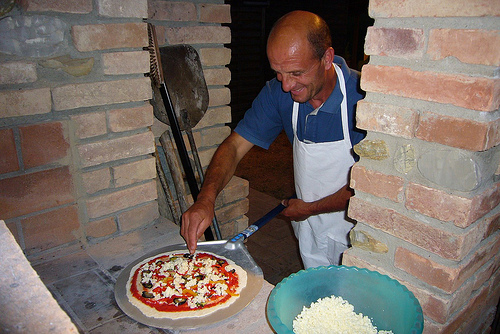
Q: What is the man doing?
A: Making pizza.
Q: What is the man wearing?
A: Apron.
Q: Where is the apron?
A: On the man.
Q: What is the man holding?
A: Handle.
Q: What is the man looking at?
A: Pizza.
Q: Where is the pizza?
A: In front of man.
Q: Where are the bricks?
A: Next to man.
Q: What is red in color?
A: Bricks.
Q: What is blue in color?
A: Shirt.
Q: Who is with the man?
A: No people.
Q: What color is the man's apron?
A: White.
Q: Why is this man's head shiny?
A: He's balding.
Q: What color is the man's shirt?
A: Blue.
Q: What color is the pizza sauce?
A: Red.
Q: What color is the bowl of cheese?
A: Blue.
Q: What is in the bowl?
A: Cheese.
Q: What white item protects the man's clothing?
A: An apron.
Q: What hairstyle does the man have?
A: Balding.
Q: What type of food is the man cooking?
A: Pizza.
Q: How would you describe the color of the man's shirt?
A: Blue.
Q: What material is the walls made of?
A: Brick and mortar.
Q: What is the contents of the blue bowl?
A: Cheese.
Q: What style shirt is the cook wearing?
A: Polo.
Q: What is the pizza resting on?
A: An oven paddle.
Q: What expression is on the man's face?
A: A smile.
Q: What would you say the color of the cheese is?
A: White.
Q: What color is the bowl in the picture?
A: Blue.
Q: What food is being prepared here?
A: Pizza.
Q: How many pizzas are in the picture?
A: One.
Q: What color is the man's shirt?
A: Blue.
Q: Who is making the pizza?
A: The man.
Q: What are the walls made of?
A: Brick.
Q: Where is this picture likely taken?
A: A restaurant.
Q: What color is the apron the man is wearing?
A: White.